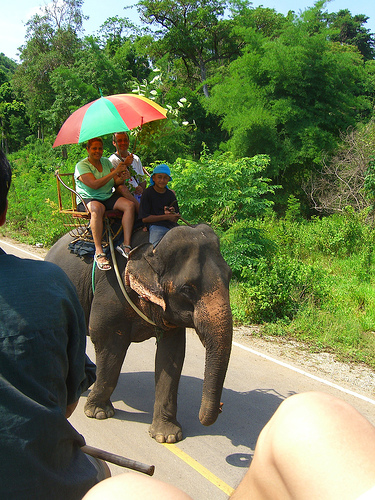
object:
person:
[74, 134, 140, 274]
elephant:
[30, 211, 235, 444]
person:
[107, 129, 149, 211]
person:
[141, 163, 186, 251]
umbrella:
[41, 90, 170, 148]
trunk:
[196, 285, 234, 428]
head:
[133, 218, 243, 427]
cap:
[149, 164, 174, 184]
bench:
[51, 176, 137, 245]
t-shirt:
[74, 157, 115, 203]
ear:
[124, 258, 167, 313]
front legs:
[148, 328, 188, 444]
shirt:
[106, 151, 145, 191]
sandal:
[92, 251, 114, 272]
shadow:
[95, 360, 311, 470]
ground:
[0, 237, 374, 499]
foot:
[147, 412, 187, 445]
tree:
[200, 17, 375, 168]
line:
[159, 432, 249, 499]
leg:
[87, 199, 111, 269]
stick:
[167, 207, 196, 229]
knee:
[84, 201, 111, 219]